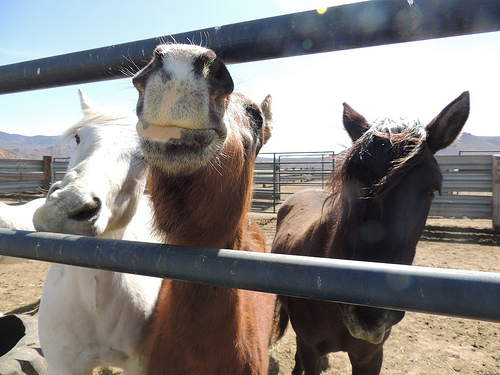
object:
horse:
[122, 41, 280, 373]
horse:
[34, 87, 176, 371]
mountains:
[1, 123, 73, 147]